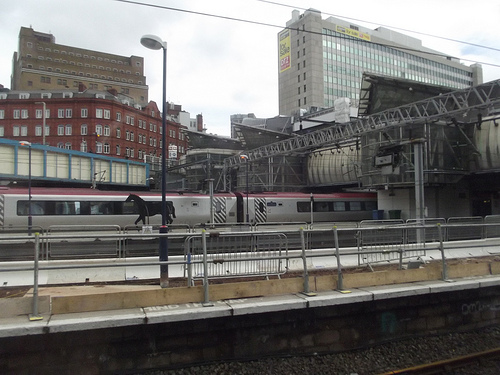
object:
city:
[0, 0, 500, 375]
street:
[0, 152, 442, 285]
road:
[127, 186, 500, 373]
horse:
[125, 193, 176, 231]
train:
[1, 186, 393, 235]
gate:
[213, 195, 268, 223]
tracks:
[4, 218, 500, 259]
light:
[140, 34, 169, 51]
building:
[0, 140, 148, 189]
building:
[0, 82, 188, 171]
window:
[81, 108, 88, 117]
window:
[66, 108, 73, 117]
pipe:
[412, 140, 424, 246]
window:
[19, 201, 136, 213]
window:
[298, 202, 370, 209]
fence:
[2, 221, 498, 339]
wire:
[122, 0, 499, 72]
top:
[2, 192, 374, 198]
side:
[6, 197, 373, 219]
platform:
[30, 281, 159, 308]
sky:
[2, 2, 500, 129]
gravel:
[145, 326, 499, 374]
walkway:
[298, 116, 499, 186]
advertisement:
[277, 30, 291, 72]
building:
[276, 9, 485, 123]